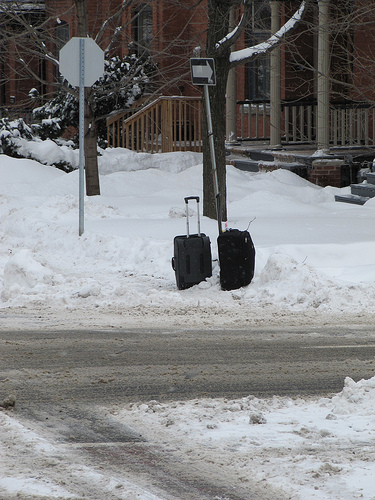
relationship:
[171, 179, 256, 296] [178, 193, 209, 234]
luggage with handle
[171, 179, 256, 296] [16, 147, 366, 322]
luggage in snow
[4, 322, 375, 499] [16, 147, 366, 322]
track in snow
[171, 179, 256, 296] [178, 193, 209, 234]
luggage with handles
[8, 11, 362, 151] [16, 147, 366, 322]
bushes in snow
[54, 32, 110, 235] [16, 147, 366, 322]
sign in snow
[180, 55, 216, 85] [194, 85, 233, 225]
sign on pole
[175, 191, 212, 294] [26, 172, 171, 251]
luggage in snow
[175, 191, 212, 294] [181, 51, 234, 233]
luggage in front of sign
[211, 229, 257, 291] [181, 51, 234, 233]
suitcase in front of sign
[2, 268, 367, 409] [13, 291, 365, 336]
road covered in sludge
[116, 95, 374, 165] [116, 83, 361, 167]
porch along porch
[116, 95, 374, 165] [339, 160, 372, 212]
porch along stairs